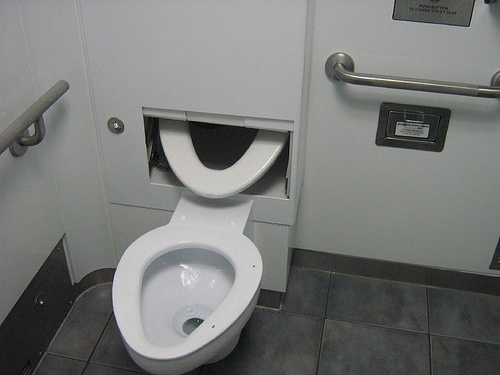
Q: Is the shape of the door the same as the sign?
A: Yes, both the door and the sign are square.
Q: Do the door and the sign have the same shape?
A: Yes, both the door and the sign are square.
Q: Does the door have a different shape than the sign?
A: No, both the door and the sign are square.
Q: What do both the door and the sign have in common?
A: The shape, both the door and the sign are square.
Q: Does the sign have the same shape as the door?
A: Yes, both the sign and the door are square.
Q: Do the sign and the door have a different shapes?
A: No, both the sign and the door are square.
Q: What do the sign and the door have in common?
A: The shape, both the sign and the door are square.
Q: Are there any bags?
A: No, there are no bags.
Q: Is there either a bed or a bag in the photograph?
A: No, there are no bags or beds.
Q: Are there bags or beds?
A: No, there are no bags or beds.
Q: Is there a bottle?
A: No, there are no bottles.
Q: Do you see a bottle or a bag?
A: No, there are no bottles or bags.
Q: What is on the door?
A: The label is on the door.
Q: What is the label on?
A: The label is on the door.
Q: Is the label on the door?
A: Yes, the label is on the door.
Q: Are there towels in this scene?
A: No, there are no towels.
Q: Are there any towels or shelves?
A: No, there are no towels or shelves.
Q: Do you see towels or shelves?
A: No, there are no towels or shelves.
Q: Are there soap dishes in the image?
A: No, there are no soap dishes.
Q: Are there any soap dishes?
A: No, there are no soap dishes.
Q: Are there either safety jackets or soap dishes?
A: No, there are no soap dishes or safety jackets.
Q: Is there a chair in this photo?
A: No, there are no chairs.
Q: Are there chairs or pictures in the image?
A: No, there are no chairs or pictures.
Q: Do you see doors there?
A: Yes, there is a door.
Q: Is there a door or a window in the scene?
A: Yes, there is a door.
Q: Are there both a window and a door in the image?
A: No, there is a door but no windows.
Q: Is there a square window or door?
A: Yes, there is a square door.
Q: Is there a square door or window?
A: Yes, there is a square door.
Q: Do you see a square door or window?
A: Yes, there is a square door.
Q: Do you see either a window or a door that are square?
A: Yes, the door is square.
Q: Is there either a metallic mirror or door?
A: Yes, there is a metal door.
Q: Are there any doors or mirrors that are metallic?
A: Yes, the door is metallic.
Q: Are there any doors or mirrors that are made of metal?
A: Yes, the door is made of metal.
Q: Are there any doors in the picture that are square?
A: Yes, there is a square door.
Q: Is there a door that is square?
A: Yes, there is a door that is square.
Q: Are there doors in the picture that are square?
A: Yes, there is a door that is square.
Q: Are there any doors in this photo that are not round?
A: Yes, there is a square door.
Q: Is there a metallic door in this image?
A: Yes, there is a metal door.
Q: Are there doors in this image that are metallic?
A: Yes, there is a metal door.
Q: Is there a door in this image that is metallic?
A: Yes, there is a door that is metallic.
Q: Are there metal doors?
A: Yes, there is a door that is made of metal.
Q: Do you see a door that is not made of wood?
A: Yes, there is a door that is made of metal.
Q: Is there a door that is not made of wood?
A: Yes, there is a door that is made of metal.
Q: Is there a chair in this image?
A: No, there are no chairs.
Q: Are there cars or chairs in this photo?
A: No, there are no chairs or cars.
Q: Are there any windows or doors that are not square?
A: No, there is a door but it is square.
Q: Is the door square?
A: Yes, the door is square.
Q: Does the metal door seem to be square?
A: Yes, the door is square.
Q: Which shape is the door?
A: The door is square.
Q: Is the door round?
A: No, the door is square.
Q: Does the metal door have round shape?
A: No, the door is square.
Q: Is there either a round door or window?
A: No, there is a door but it is square.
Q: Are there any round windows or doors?
A: No, there is a door but it is square.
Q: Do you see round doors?
A: No, there is a door but it is square.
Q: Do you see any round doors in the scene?
A: No, there is a door but it is square.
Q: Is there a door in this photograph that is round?
A: No, there is a door but it is square.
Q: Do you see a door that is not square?
A: No, there is a door but it is square.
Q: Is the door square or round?
A: The door is square.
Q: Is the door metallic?
A: Yes, the door is metallic.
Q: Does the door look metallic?
A: Yes, the door is metallic.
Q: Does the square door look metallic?
A: Yes, the door is metallic.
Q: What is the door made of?
A: The door is made of metal.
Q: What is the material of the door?
A: The door is made of metal.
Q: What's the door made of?
A: The door is made of metal.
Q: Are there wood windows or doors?
A: No, there is a door but it is metallic.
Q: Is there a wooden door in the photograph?
A: No, there is a door but it is metallic.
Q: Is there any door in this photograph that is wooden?
A: No, there is a door but it is metallic.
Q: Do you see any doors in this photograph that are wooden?
A: No, there is a door but it is metallic.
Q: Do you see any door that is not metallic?
A: No, there is a door but it is metallic.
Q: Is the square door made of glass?
A: No, the door is made of metal.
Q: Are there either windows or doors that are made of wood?
A: No, there is a door but it is made of metal.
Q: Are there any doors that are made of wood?
A: No, there is a door but it is made of metal.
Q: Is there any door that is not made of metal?
A: No, there is a door but it is made of metal.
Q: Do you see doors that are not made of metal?
A: No, there is a door but it is made of metal.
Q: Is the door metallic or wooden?
A: The door is metallic.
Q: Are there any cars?
A: No, there are no cars.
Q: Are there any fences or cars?
A: No, there are no cars or fences.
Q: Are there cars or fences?
A: No, there are no cars or fences.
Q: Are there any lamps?
A: No, there are no lamps.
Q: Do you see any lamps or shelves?
A: No, there are no lamps or shelves.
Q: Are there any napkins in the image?
A: No, there are no napkins.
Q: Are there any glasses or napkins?
A: No, there are no napkins or glasses.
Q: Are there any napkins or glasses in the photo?
A: No, there are no napkins or glasses.